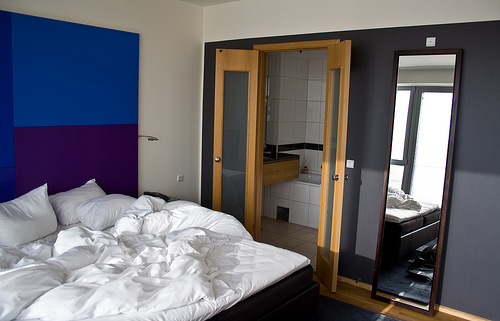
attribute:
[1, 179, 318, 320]
bed — not made, unmade, messy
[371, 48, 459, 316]
mirror — tall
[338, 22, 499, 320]
wall — painted gray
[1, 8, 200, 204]
wall — purple, blue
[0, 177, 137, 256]
pillows — white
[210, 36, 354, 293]
doors — brown, open, tan, made of wood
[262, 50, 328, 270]
bathroom — dark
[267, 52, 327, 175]
bathroom wall — tiled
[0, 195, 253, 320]
sheets — white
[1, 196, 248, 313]
comforter — white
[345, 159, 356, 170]
light switch — small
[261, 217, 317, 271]
floor — tiled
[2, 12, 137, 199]
headboard — tall